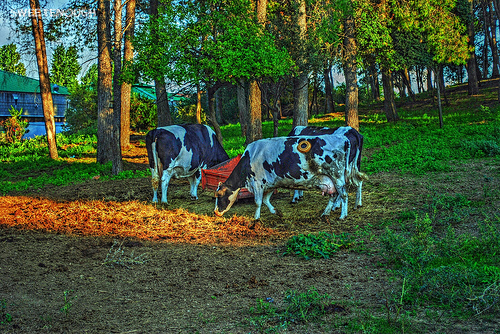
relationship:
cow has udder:
[208, 131, 348, 225] [316, 176, 338, 196]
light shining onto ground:
[0, 193, 278, 243] [0, 76, 500, 333]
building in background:
[0, 70, 69, 139] [3, 2, 497, 170]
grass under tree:
[31, 105, 494, 167] [205, 0, 290, 134]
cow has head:
[208, 131, 348, 225] [213, 177, 243, 222]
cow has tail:
[208, 131, 348, 225] [339, 137, 356, 182]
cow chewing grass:
[208, 131, 348, 225] [31, 105, 494, 167]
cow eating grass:
[141, 121, 237, 206] [31, 105, 494, 167]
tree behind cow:
[205, 0, 290, 134] [208, 131, 348, 225]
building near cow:
[0, 70, 69, 139] [208, 131, 348, 225]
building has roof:
[6, 73, 80, 135] [0, 69, 73, 99]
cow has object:
[208, 131, 348, 225] [295, 139, 311, 155]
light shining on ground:
[0, 193, 278, 243] [0, 76, 500, 333]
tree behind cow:
[205, 0, 290, 134] [141, 121, 237, 206]